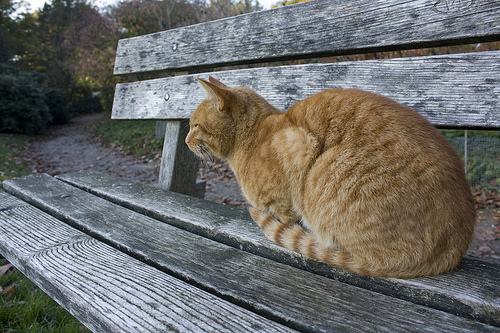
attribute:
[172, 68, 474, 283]
cat — orange, tabby, sitting, looking, curled, golden, lying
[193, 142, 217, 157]
whisker — white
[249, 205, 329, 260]
tail — striped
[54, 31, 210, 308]
bench — wooden, wood, grey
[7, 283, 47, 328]
grass — green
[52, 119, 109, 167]
path — dirty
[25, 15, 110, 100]
tree — lush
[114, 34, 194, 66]
slat — wood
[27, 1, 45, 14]
sky — sunny